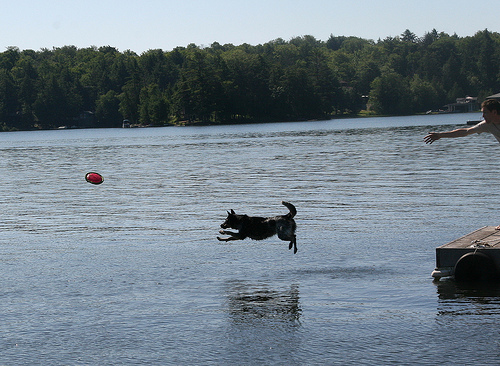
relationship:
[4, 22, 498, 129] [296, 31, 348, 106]
line on tree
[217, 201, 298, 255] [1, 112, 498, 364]
dog in water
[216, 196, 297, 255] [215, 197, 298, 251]
dog has black body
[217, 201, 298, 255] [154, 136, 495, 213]
dog jumping into lake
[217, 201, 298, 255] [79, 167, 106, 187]
dog chasing ball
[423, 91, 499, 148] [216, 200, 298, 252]
person throwing toy in front of dog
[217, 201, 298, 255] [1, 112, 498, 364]
dog reflected in water